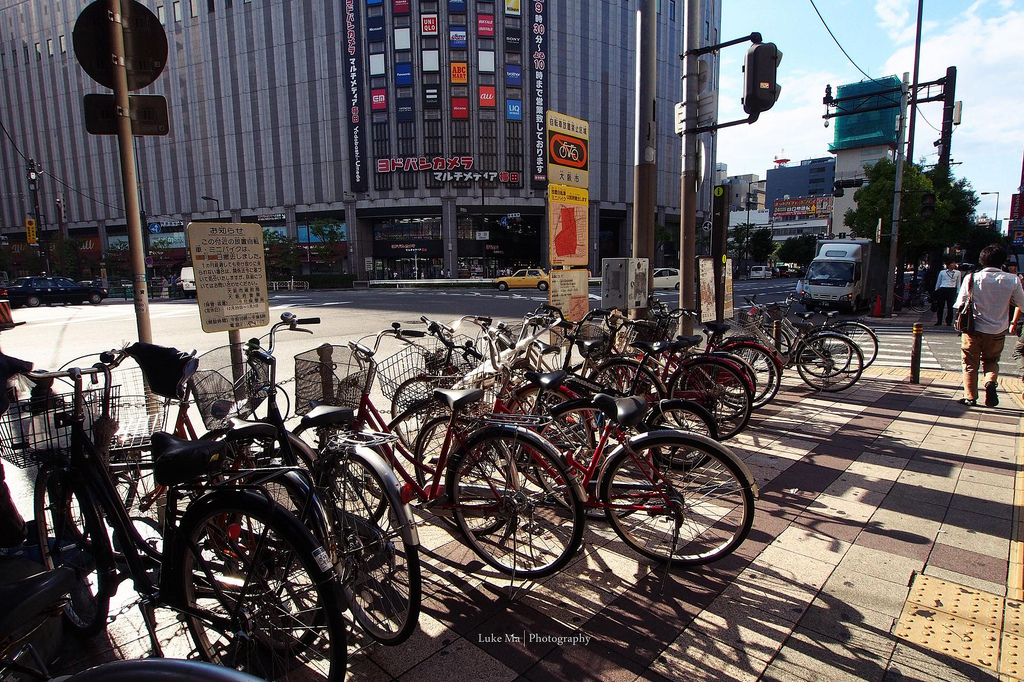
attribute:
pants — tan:
[950, 241, 1020, 407]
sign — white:
[181, 210, 273, 340]